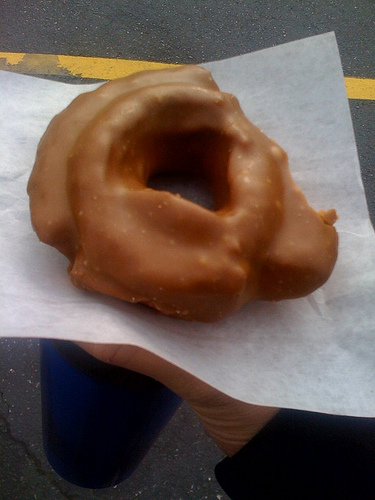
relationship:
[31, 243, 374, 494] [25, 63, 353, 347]
person holding doughnut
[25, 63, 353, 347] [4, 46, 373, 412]
doughnut on top of paper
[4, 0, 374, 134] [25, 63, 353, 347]
road near doughnut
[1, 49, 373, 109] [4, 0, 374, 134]
line in road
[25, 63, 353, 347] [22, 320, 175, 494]
doughnut on top of cup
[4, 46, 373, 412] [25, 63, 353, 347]
paper underneath doughnut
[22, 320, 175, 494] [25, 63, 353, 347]
cup underneath doughnut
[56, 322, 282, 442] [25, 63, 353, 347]
thumb near doughnut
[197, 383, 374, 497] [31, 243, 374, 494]
sleeve on person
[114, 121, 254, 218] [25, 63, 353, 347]
hole in doughnut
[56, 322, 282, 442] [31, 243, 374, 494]
thumb on person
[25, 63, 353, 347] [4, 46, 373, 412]
doughnut on white paper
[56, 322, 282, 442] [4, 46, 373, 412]
thumb underneath paper